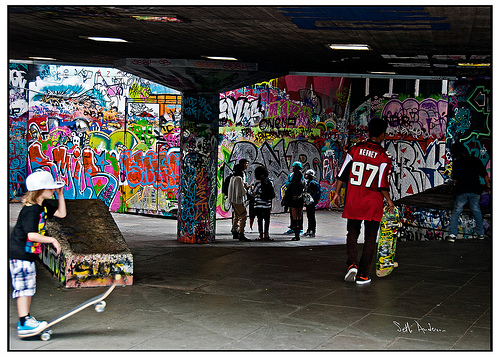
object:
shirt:
[339, 142, 389, 222]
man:
[328, 118, 405, 286]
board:
[373, 200, 405, 275]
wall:
[0, 60, 492, 220]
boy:
[9, 166, 72, 335]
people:
[305, 167, 325, 236]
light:
[322, 42, 370, 51]